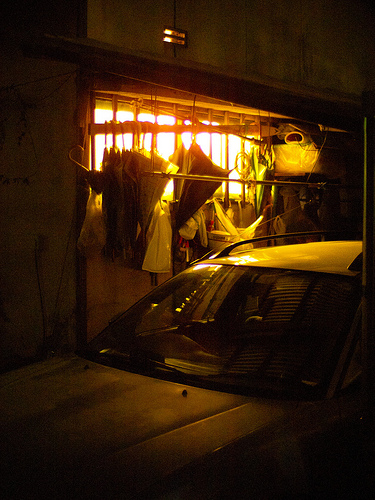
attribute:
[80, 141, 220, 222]
umbrellas — hanging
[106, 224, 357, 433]
car — upper, here, side, white, parked, old fashioned, infront, sectioned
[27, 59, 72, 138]
wall — here, white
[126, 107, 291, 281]
light — reflecting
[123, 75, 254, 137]
rod — brown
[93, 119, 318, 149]
pole — brown, atop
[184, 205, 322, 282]
cover — white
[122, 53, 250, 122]
line — overhead, bright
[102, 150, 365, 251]
rail — across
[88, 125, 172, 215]
stand — here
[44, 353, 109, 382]
hole — small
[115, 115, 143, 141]
hand — brown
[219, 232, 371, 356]
bonnet — here, present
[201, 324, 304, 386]
wipers — sectioned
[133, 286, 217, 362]
window — here, present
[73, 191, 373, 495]
vehicle — parked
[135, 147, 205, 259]
umbrella — hanging